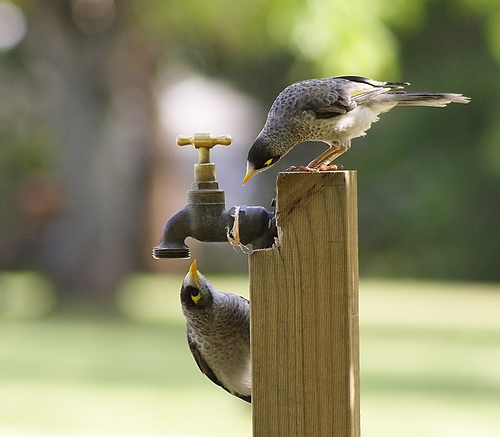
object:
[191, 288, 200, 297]
eye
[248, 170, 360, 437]
post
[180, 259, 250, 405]
bird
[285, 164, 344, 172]
claws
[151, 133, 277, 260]
faucet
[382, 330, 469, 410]
ground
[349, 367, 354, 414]
light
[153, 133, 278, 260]
brass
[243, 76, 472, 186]
bird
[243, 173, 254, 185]
beak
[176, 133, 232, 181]
handle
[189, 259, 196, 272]
beak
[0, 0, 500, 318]
background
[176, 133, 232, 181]
spigot